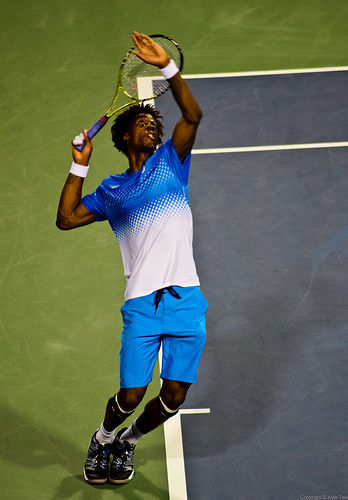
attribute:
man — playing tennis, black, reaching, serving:
[54, 29, 209, 486]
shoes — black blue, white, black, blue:
[84, 424, 136, 485]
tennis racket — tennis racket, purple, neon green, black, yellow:
[73, 34, 183, 151]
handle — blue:
[70, 115, 109, 151]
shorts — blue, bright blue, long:
[118, 285, 210, 388]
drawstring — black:
[150, 285, 182, 312]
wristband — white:
[155, 58, 180, 82]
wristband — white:
[67, 159, 91, 179]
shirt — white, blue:
[81, 138, 199, 301]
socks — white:
[94, 419, 146, 447]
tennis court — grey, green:
[1, 1, 346, 499]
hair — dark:
[108, 99, 163, 150]